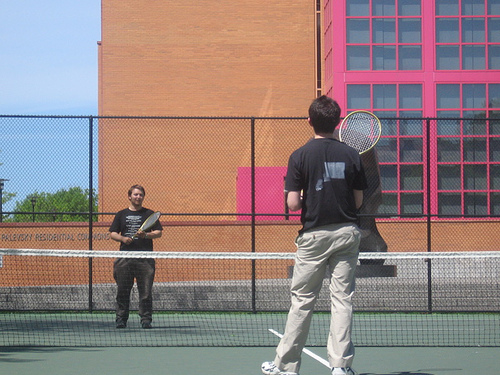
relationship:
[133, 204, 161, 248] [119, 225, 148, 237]
racket with hands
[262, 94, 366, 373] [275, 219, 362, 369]
person wearing pants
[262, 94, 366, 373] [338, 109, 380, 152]
person holding tennis racket